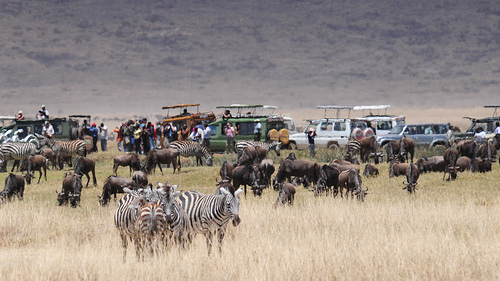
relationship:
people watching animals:
[221, 115, 263, 145] [110, 184, 242, 254]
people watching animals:
[166, 122, 208, 139] [143, 140, 215, 170]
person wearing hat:
[303, 123, 322, 159] [303, 125, 313, 135]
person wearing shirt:
[223, 121, 239, 153] [222, 125, 235, 135]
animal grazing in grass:
[0, 170, 30, 200] [1, 137, 498, 279]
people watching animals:
[7, 102, 475, 149] [0, 128, 500, 261]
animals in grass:
[8, 120, 494, 276] [1, 137, 498, 279]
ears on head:
[201, 181, 248, 204] [218, 182, 243, 226]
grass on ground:
[1, 137, 498, 279] [4, 122, 498, 278]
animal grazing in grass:
[64, 172, 84, 205] [1, 137, 498, 279]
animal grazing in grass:
[55, 171, 71, 203] [1, 137, 498, 279]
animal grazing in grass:
[96, 170, 111, 205] [1, 137, 498, 279]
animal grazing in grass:
[103, 171, 143, 198] [1, 137, 498, 279]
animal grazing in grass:
[130, 167, 152, 194] [1, 137, 498, 279]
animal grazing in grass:
[109, 150, 144, 177] [1, 137, 498, 279]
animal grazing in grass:
[143, 143, 183, 174] [1, 137, 498, 279]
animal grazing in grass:
[168, 136, 214, 167] [1, 137, 498, 279]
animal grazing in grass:
[235, 135, 284, 159] [1, 137, 498, 279]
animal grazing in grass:
[213, 157, 235, 186] [1, 137, 498, 279]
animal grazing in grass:
[228, 162, 264, 199] [1, 137, 498, 279]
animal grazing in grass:
[259, 152, 275, 187] [1, 137, 498, 279]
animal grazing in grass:
[274, 179, 296, 203] [1, 137, 498, 279]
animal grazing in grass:
[273, 157, 315, 180] [1, 137, 498, 279]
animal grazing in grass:
[329, 158, 363, 175] [1, 137, 498, 279]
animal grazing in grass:
[338, 165, 370, 204] [1, 137, 498, 279]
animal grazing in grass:
[361, 160, 378, 175] [1, 137, 498, 279]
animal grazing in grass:
[401, 159, 422, 192] [1, 137, 498, 279]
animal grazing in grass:
[438, 144, 458, 179] [1, 137, 498, 279]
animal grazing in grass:
[456, 133, 479, 160] [1, 137, 498, 279]